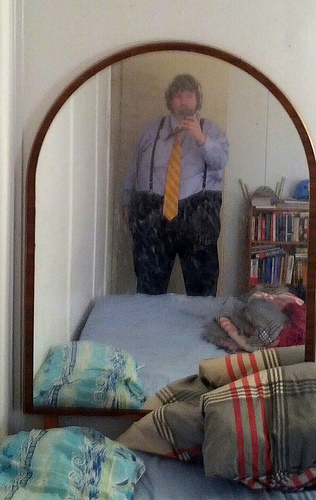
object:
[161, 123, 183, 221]
tie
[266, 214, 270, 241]
books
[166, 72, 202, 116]
head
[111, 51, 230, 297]
door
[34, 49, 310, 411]
mirror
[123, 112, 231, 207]
shirt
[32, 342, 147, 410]
reflection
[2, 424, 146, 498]
pillow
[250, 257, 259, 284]
book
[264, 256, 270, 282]
book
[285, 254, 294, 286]
book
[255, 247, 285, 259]
book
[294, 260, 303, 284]
book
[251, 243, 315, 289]
second shelf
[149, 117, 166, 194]
black suspenders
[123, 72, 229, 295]
man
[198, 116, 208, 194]
suspenders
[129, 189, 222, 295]
black pants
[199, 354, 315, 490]
multi-tone comforter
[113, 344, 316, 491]
blanket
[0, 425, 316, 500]
bed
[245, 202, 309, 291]
bookshelf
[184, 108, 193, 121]
phone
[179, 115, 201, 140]
man's hand